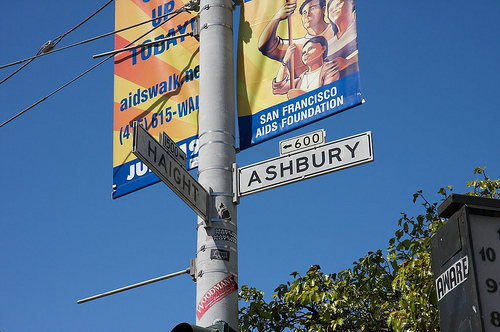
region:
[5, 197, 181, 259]
the blue sky in the background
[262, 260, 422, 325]
many tree leaves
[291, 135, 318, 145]
the nummber 600 in black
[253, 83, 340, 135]
it says San Francisco Aids Foundation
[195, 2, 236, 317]
a thick vertical tube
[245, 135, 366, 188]
it says : Ashbury in black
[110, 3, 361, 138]
a flyer of Aids Help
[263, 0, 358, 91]
the image of a human family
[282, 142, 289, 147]
an arrow indicating to the left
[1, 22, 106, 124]
the electrical wiring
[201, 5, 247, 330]
concrete pole holding signs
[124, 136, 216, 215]
street sign on pole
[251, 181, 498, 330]
tree growing on right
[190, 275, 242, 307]
red sticker on sign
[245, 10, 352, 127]
flag on concrete pole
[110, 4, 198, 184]
flag on concrete pole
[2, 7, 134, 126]
electric lines connecting to pole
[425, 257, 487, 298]
aware sticker on box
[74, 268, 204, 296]
pole sticking out from post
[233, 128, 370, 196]
black and white street sign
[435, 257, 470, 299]
black and white sticker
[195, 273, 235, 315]
sticker on the pole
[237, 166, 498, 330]
leaves of a tree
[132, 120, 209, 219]
this is a street sign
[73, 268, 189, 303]
metal rod sticking out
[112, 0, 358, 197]
sign for an aids walk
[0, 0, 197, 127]
cables in the air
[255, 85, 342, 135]
the text is white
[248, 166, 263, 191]
letter a on sign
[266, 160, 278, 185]
letter s on sign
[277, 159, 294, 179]
letter h on sign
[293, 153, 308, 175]
letter b on sign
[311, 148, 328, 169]
letter u on sign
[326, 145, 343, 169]
letter r on sign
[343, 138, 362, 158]
letter y on sign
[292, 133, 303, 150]
number six on sign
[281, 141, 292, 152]
arrow pointing left on sign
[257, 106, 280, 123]
word san on sign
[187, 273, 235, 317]
red sticker on a street pole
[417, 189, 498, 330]
corner of a square black clock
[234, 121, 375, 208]
a street sign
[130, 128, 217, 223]
a white and black sign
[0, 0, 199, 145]
cables extending from the pole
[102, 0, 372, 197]
banner on the street pole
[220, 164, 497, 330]
top of a green tree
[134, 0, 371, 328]
metal pole with street signs on it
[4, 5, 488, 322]
bright blue clear sky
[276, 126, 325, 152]
numbers on top of the street sign